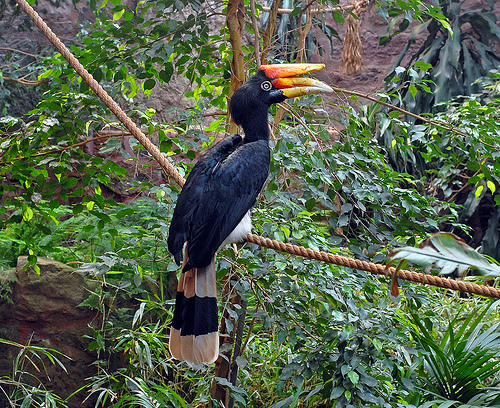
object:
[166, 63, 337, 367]
bird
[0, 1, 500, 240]
dirt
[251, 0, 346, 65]
plants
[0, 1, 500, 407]
tree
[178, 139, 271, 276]
wings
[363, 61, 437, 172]
plant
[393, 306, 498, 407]
plant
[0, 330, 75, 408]
plant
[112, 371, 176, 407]
plant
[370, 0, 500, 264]
plant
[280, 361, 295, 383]
leaf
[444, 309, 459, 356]
leaf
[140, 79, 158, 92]
leaf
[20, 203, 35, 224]
leaf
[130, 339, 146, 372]
leaf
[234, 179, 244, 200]
feather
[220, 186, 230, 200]
feather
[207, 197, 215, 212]
feather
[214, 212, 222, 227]
feather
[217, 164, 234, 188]
feather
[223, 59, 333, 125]
head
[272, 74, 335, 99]
beak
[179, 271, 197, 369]
tail feather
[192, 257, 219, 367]
tail feather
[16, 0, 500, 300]
rope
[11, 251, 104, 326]
rock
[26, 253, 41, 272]
leaves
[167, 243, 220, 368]
tail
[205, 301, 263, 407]
vegetated grounds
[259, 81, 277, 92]
ring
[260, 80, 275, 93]
eye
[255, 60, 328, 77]
appendage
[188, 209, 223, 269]
black feathers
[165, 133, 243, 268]
wing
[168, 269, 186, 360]
tail feather